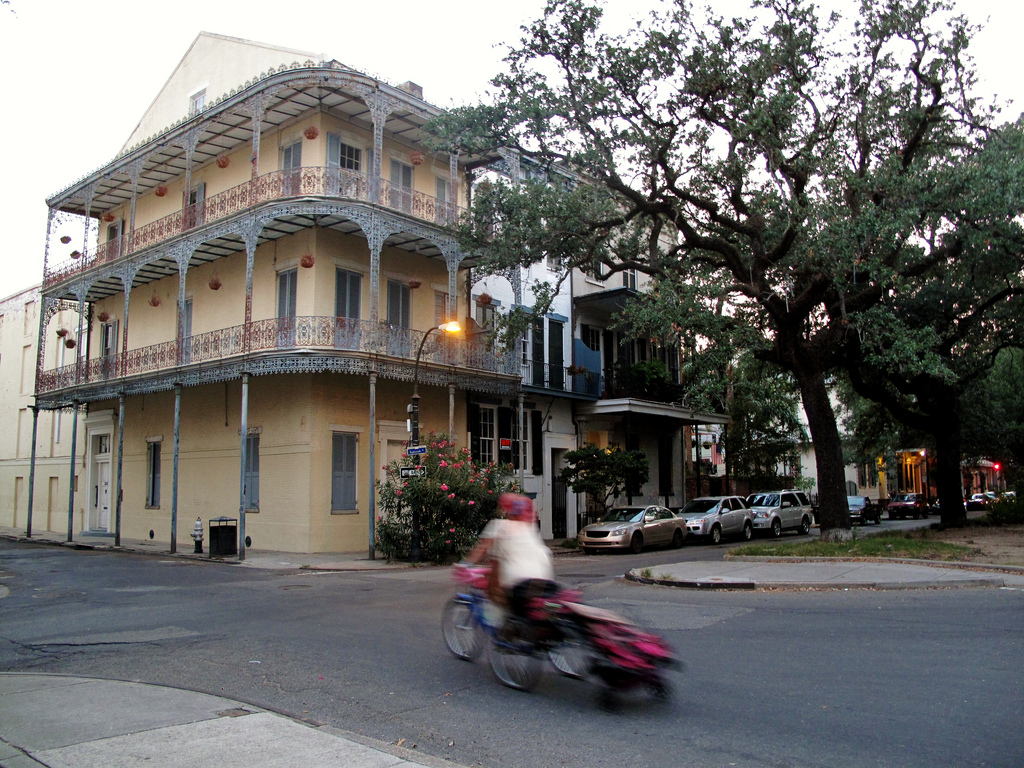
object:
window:
[135, 437, 167, 514]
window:
[172, 284, 195, 362]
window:
[273, 262, 302, 348]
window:
[377, 268, 418, 357]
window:
[432, 275, 461, 364]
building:
[693, 190, 884, 578]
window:
[335, 131, 367, 199]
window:
[276, 137, 308, 196]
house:
[52, 29, 505, 573]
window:
[266, 266, 306, 348]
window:
[325, 422, 366, 525]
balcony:
[297, 269, 532, 363]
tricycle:
[435, 557, 616, 689]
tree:
[458, 4, 932, 538]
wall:
[568, 321, 604, 399]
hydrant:
[187, 516, 207, 552]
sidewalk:
[9, 531, 753, 574]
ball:
[206, 274, 222, 291]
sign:
[406, 444, 428, 456]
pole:
[406, 322, 448, 531]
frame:
[464, 401, 504, 477]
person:
[448, 490, 564, 659]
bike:
[433, 557, 585, 693]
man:
[454, 480, 564, 644]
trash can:
[203, 515, 243, 558]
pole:
[237, 379, 250, 559]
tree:
[419, 4, 1009, 545]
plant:
[364, 432, 516, 566]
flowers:
[438, 482, 454, 493]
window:
[236, 431, 259, 512]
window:
[329, 262, 360, 348]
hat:
[495, 487, 539, 523]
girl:
[452, 484, 567, 645]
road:
[0, 507, 1023, 761]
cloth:
[449, 562, 498, 585]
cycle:
[431, 550, 611, 705]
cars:
[666, 492, 757, 549]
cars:
[736, 490, 815, 539]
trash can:
[203, 514, 239, 555]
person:
[448, 487, 564, 664]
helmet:
[496, 493, 539, 523]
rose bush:
[373, 431, 529, 561]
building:
[469, 132, 723, 562]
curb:
[623, 558, 1009, 589]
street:
[4, 506, 1024, 762]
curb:
[116, 532, 425, 580]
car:
[575, 501, 691, 554]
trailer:
[512, 580, 686, 714]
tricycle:
[433, 549, 552, 688]